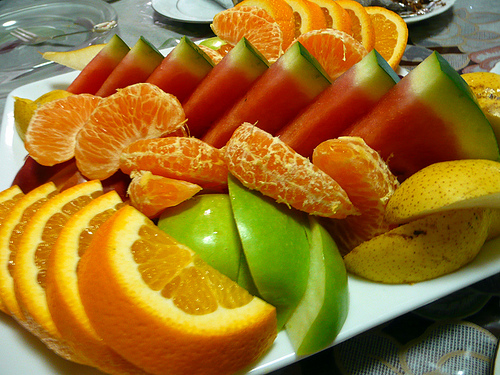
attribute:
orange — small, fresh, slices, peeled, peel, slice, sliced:
[7, 167, 220, 344]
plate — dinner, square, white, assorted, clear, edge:
[355, 291, 401, 327]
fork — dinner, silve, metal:
[32, 24, 65, 56]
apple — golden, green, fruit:
[195, 197, 318, 279]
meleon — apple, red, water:
[342, 35, 462, 135]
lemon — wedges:
[335, 169, 453, 318]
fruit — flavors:
[25, 33, 465, 327]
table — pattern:
[455, 44, 479, 63]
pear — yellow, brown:
[395, 159, 453, 225]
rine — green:
[235, 213, 295, 295]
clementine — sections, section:
[124, 128, 282, 230]